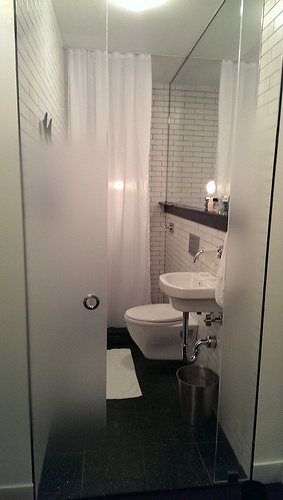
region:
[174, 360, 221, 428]
A silver trash can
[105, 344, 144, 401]
A rectangular white mat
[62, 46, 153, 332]
A white shower curtain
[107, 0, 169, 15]
A light is turned on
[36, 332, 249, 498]
Black tiles are on the floor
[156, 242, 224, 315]
A faucet over a white sink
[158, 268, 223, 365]
Silver pipes under the sink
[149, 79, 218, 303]
White tiles on the wall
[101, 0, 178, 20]
A light is on the ceiling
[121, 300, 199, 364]
A white porcelain toilet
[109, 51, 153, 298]
white bathtub curtain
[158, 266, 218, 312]
white bathroom sink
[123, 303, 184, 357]
bathroom toilet seat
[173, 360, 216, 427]
metal trash bin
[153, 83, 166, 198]
white painted brick in bathroom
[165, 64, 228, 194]
mirror in a bathroom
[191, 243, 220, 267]
faucet on top of bathroom sink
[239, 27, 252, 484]
part of a glass door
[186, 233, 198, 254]
automatic flush button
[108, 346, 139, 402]
bathroom towel on floor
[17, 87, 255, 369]
this is inside a bathroom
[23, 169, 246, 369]
this is a mirror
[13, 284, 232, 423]
this is a reflection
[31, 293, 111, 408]
this part fo the mirror is fogged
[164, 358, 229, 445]
this is a trash bin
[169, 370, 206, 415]
the trash bin is metal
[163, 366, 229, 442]
the trash bin is silver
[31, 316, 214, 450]
the mirror is made of glass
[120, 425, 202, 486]
the ground here is tile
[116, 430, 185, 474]
the tile is speckled black and white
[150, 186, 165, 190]
tile on the wall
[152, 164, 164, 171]
tile on the wall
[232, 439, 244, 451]
tile on the wall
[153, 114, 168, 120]
tile on the wall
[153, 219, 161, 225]
tile on the wall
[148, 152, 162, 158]
tile on the wall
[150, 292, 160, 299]
tile on the wall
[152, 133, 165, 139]
tile on the wall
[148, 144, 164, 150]
tile on the wall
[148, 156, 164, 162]
tile on the wall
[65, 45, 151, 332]
the shower curtain is white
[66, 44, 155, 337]
the shower curtain is white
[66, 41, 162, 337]
the shower curtain is white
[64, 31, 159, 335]
the shower curtain is white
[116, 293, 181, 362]
toilet cover is down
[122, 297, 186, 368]
toilet cover is down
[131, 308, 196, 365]
toilet cover is down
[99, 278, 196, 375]
toilet cover is down